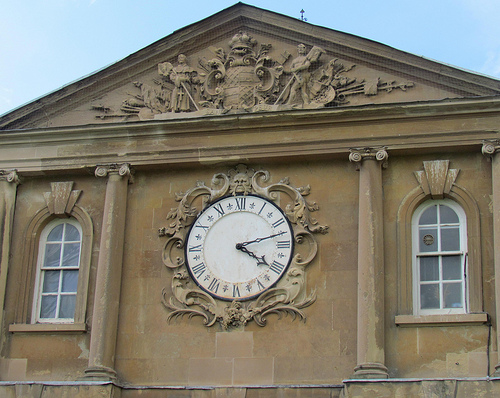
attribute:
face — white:
[203, 211, 278, 286]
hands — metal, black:
[232, 230, 288, 269]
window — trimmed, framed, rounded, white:
[6, 156, 491, 334]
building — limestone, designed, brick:
[0, 1, 500, 396]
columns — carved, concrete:
[92, 157, 404, 384]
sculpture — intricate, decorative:
[141, 29, 383, 110]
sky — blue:
[0, 2, 499, 111]